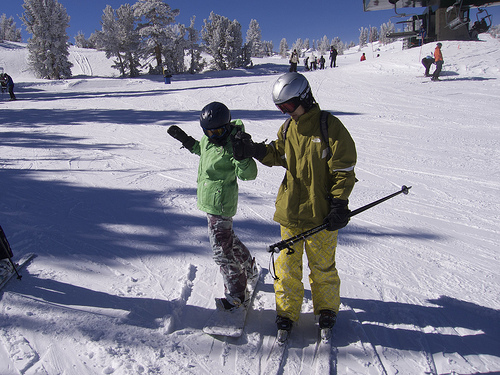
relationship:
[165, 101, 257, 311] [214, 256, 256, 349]
boy balancing on snowboard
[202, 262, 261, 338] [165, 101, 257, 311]
snowbaord under boy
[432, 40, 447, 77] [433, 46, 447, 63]
person wearing jacket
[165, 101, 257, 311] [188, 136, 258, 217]
boy wearing green jacket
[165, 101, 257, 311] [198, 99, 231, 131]
boy wearing helmet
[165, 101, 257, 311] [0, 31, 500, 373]
boy on slope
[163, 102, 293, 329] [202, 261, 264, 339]
boy standing on snowboard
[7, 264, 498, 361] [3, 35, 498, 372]
people's shadow on snow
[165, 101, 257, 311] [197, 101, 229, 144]
boy wearing helmet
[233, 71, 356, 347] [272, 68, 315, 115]
person wearing helmet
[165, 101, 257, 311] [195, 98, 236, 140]
boy wearing helmet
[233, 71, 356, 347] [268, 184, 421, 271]
person holding poles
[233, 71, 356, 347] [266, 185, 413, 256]
person holding ski pole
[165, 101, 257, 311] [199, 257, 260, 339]
boy standing on snowboard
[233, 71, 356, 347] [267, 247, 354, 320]
person wearing yellow pants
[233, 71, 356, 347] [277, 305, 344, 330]
person wearing boots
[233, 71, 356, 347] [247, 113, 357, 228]
person wearing coat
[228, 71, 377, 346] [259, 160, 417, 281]
person holding poles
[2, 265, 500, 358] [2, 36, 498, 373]
people's shadow on ground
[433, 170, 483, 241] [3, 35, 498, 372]
ski tracks on snow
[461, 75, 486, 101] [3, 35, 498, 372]
ski tracks on snow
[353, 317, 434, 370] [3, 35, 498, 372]
ski tracks on snow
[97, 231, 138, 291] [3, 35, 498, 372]
ski tracks on snow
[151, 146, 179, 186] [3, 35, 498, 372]
ski tracks on snow